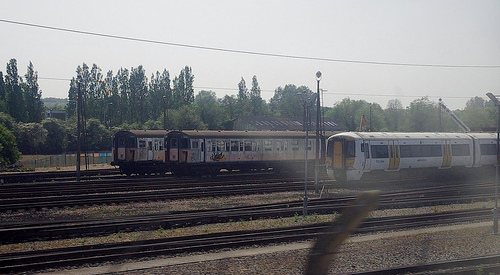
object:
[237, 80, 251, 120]
trees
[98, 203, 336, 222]
tracks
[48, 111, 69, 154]
trees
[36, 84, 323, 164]
fence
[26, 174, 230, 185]
tracks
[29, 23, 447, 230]
scene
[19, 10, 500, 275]
photo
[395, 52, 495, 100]
sky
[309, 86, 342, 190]
post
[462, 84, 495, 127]
trees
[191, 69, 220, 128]
trees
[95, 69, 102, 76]
leaves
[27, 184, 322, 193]
tracks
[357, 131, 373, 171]
door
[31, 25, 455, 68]
wire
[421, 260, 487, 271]
tracks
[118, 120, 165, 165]
cars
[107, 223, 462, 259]
tracks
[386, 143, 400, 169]
door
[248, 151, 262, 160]
graffiti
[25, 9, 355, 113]
sky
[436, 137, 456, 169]
doors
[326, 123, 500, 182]
trains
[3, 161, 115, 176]
tracks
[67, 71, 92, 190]
pole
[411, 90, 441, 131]
trees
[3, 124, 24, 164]
bush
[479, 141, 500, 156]
windows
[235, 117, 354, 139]
building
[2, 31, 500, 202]
distance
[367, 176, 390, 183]
wheels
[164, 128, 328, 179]
train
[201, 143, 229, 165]
graffiti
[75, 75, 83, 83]
light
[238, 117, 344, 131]
roof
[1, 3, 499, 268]
daytime